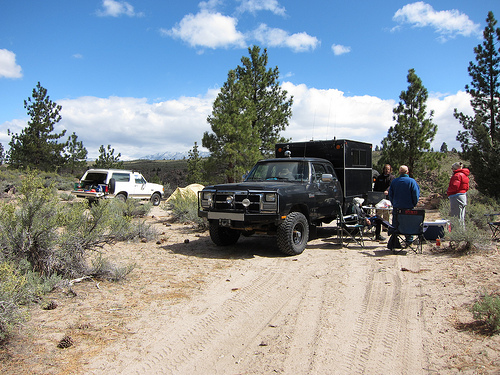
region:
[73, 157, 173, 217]
The vehicle is white.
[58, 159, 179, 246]
The vehicle is parked.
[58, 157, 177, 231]
Tailgate of vehicle is open.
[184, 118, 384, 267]
The truck is black.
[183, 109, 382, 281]
The truck is parked.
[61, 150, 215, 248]
A tent is next to the vehicle.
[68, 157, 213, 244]
The tent is yellow.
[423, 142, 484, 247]
The woman is standing.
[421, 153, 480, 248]
The woman is wearing a jacket.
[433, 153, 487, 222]
The jacket is red.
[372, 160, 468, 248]
four people at a camping site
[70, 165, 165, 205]
a white truck with camping equipment in the back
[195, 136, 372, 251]
a black truck parked on a dirt road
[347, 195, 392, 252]
a woman sitting in a chair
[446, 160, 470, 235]
a woman in a red coat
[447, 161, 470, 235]
a woman standing on camping ground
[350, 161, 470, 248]
two couples at a camping site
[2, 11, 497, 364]
people in the woods camping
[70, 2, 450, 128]
white clouds in the sky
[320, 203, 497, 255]
camping chairs and supplies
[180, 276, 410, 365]
tracks in the dirt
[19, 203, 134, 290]
dried bare bushes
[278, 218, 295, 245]
thick black tread on a tire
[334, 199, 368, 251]
a metal and cloth folding chair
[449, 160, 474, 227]
a person wearing a red parka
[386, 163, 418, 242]
a ma wearing a blue jacket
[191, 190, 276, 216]
a metal rack on the front of the truck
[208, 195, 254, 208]
shiny round headlights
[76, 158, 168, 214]
a white suv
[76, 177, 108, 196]
items the back of an suv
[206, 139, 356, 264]
black truck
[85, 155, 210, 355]
white truck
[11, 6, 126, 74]
whiet clouds in blue sky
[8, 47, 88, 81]
whiet clouds in blue sky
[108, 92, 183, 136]
whiet clouds in blue sky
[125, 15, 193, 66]
whiet clouds in blue sky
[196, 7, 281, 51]
whiet clouds in blue sky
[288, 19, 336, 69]
whiet clouds in blue sky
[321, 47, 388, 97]
whiet clouds in blue sky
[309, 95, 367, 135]
whiet clouds in blue sky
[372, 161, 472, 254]
people wearing coats in the outdoors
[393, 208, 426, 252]
a blue folding chair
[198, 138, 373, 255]
a truck with camping stuff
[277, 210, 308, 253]
a front wheel of the truck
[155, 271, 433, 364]
tire tracks in the sand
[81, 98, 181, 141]
white clouds in the background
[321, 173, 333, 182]
a side mirror of the truck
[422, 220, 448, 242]
a blue cooler on the ground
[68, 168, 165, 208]
a white vehicle in the background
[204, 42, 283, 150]
tall trees in the background